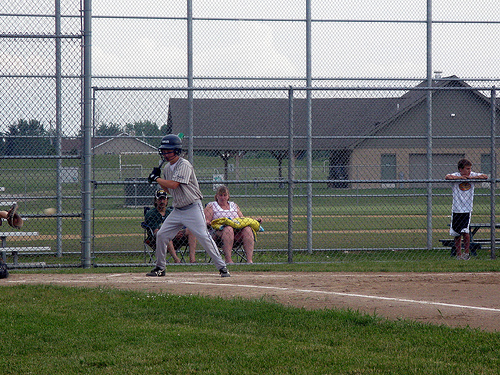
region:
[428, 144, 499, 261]
young boy is watching baseball game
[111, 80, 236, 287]
a ball player at bat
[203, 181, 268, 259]
the lady is holding a yellow blanket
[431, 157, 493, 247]
the boy is looking thru the fence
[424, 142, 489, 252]
the boy has on a white shirt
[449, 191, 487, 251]
the boy has on black & white shorts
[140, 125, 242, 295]
the batter is wearing a helmt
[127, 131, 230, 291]
the batter's shirt is striped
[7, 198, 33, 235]
the catcher's mitt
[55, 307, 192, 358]
the grass is green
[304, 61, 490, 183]
the building is large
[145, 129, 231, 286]
boy with bat in hand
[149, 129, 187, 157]
helmet on batter's head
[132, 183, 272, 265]
two people sitting in chairs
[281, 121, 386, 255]
chain link fence behind field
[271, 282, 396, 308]
white line in dirt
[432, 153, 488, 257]
boy leaning on fence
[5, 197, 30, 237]
mitt on hand behind batter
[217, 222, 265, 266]
bare legs on woman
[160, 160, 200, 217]
striped baseball uniform shirt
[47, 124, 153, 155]
building top behind hill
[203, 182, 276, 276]
woman sitting in chair with yellow blanket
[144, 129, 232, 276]
The batter looking at the ball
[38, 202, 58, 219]
The ball in the air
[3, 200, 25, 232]
The catcher's mitt about to catch the ball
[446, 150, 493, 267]
The boy leaning against the fence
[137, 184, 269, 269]
The people sitting behind the fence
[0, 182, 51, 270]
The edge of the bleachers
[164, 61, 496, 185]
The closest building in the background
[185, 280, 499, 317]
The line that leads to first base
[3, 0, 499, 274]
The fence behind the batter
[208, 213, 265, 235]
The blanket on the woman's legs